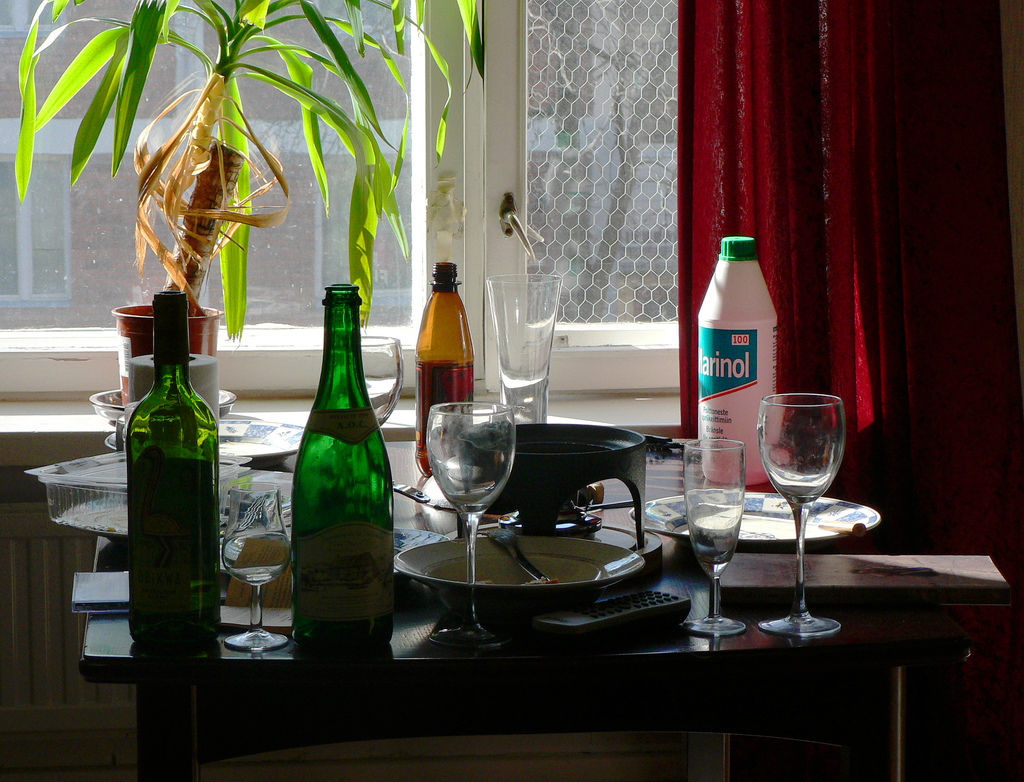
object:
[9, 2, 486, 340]
plant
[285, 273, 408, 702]
bottle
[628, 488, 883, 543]
plate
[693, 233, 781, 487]
bottle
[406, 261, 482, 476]
bottle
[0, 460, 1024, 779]
table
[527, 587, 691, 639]
remote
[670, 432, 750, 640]
glass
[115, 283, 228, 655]
bottle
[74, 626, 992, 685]
edge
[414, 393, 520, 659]
glass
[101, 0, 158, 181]
leaf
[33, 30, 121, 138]
leaf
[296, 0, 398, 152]
leaf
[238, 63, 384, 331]
leaf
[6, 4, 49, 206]
leaf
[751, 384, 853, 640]
wine glass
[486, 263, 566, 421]
glass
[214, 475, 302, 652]
glass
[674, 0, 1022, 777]
curtain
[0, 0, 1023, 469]
window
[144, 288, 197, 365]
pot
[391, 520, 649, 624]
plate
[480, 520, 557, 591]
fork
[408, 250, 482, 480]
liquor bottle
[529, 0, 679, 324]
wire